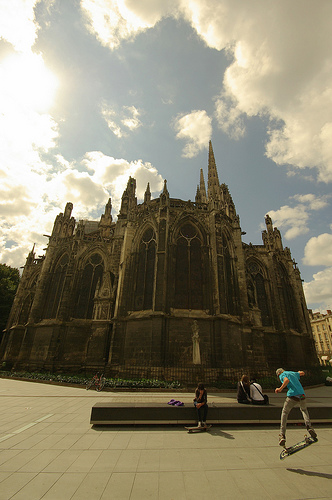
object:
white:
[0, 63, 50, 143]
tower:
[14, 200, 78, 373]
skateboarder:
[193, 382, 209, 429]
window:
[70, 243, 108, 321]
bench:
[89, 399, 332, 426]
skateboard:
[278, 434, 319, 460]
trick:
[279, 434, 319, 470]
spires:
[207, 140, 221, 201]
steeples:
[98, 197, 113, 226]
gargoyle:
[42, 233, 51, 250]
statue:
[191, 320, 201, 365]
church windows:
[168, 209, 211, 312]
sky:
[0, 0, 332, 315]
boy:
[274, 368, 318, 447]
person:
[249, 378, 266, 406]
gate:
[0, 357, 328, 388]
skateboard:
[183, 424, 212, 433]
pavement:
[0, 377, 332, 500]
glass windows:
[134, 227, 156, 311]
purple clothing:
[167, 397, 185, 407]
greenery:
[0, 368, 183, 388]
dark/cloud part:
[254, 0, 332, 102]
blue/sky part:
[154, 65, 205, 109]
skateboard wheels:
[304, 433, 308, 438]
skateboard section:
[292, 441, 304, 450]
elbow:
[284, 377, 290, 382]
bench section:
[90, 406, 332, 420]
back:
[237, 381, 249, 400]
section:
[133, 444, 161, 473]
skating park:
[0, 395, 332, 500]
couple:
[236, 374, 265, 405]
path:
[0, 377, 332, 397]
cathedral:
[0, 140, 325, 389]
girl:
[236, 374, 250, 404]